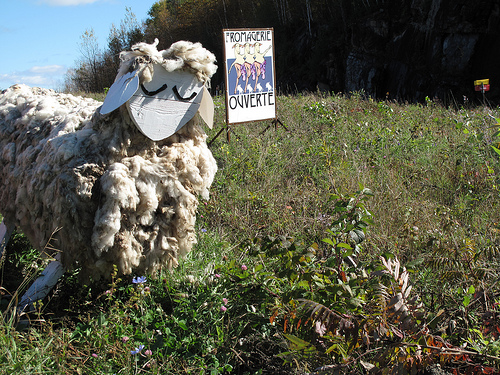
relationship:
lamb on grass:
[0, 36, 218, 306] [14, 277, 420, 365]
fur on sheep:
[22, 149, 146, 218] [0, 35, 222, 311]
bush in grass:
[304, 108, 477, 257] [258, 272, 395, 353]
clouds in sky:
[1, 0, 157, 93] [0, 0, 43, 36]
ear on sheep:
[100, 65, 140, 115] [0, 36, 238, 296]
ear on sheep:
[200, 86, 216, 129] [0, 36, 238, 296]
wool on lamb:
[1, 40, 219, 298] [0, 36, 218, 306]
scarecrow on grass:
[0, 39, 218, 303] [395, 143, 469, 214]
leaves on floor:
[256, 242, 498, 374] [1, 95, 498, 370]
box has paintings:
[125, 61, 206, 118] [135, 74, 198, 105]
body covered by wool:
[0, 30, 233, 315] [28, 71, 159, 268]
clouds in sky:
[1, 0, 157, 93] [17, 16, 97, 65]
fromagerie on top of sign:
[220, 30, 275, 42] [220, 23, 278, 123]